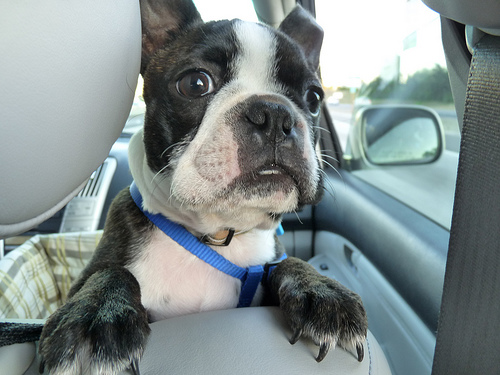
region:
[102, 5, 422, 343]
black and white dog in vehicle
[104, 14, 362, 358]
blue leash on black and white dog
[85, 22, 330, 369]
black and white dog standing on car seat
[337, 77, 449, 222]
side car mirror with sky reflected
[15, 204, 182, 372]
basket behind black and white dog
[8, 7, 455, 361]
grey car interior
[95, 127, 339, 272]
dog with collar and blue leash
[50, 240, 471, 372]
dogs black paws on seat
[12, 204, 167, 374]
plaid basket in background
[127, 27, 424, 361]
black and white dog looking back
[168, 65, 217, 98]
the eye of a dog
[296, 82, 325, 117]
the eye of a dog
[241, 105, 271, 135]
the nostril of a dog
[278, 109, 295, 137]
the nostril of a dog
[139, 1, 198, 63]
the ear of a dog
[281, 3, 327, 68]
the ear of a dog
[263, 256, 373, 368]
the leg of a dog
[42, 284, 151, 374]
the leg of a dog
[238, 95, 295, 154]
the nose of a dog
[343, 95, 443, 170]
a side mirror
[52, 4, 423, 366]
dog traveling in car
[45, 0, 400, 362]
nice dog traveling in car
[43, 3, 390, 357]
adorable dog traveling in car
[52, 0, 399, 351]
friendly dog traveling in car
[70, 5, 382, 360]
cute dog traveling in car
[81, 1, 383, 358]
cuddly dog traveling in car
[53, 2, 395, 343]
curious dog traveling in car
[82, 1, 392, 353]
alert dog traveling in car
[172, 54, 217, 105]
right eye of a dog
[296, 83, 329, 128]
left eye of a dog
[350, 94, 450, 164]
A white side mirror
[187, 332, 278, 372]
A white car seat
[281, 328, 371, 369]
Long s harp dog paws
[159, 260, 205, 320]
White colored body fur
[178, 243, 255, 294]
Blue colored neck tag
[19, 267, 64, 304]
A yellow checked basket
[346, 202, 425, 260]
Grey colored car sides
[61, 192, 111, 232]
A white colored control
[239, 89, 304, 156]
Black colored dog paws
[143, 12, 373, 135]
Black and white face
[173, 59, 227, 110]
the eye of a dog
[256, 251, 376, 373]
the paw of a dog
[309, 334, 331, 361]
a black dog's claw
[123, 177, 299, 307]
a blue dog collar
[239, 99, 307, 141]
the black nose of a dog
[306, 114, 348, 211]
whiskers of the dog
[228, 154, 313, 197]
the mouth of the dog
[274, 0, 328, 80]
the ear of the dog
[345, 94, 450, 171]
a side view mirror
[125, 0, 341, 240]
the head of a dog